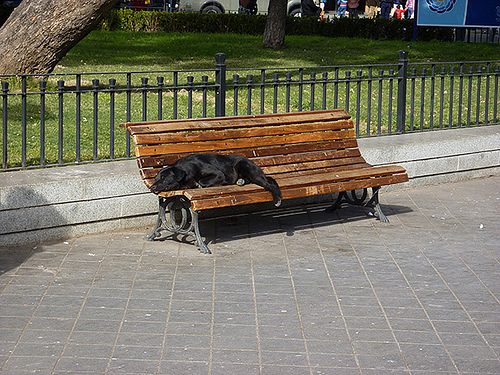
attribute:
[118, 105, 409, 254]
bench — wooden, brown, color brown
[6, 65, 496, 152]
fence — black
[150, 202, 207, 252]
leg — iron